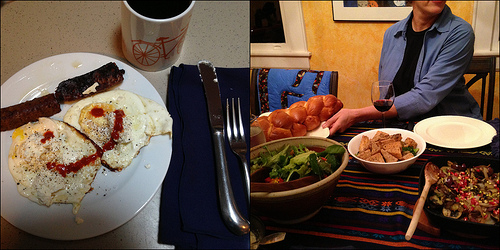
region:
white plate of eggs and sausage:
[1, 46, 173, 241]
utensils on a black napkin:
[195, 54, 258, 246]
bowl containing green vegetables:
[248, 135, 349, 203]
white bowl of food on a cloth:
[348, 120, 426, 172]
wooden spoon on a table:
[405, 156, 444, 246]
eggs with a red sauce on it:
[14, 120, 99, 195]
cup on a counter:
[120, 3, 195, 70]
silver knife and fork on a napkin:
[189, 56, 258, 236]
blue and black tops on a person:
[377, 15, 477, 111]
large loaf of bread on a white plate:
[244, 90, 351, 135]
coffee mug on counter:
[108, 0, 228, 79]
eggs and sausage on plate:
[14, 55, 162, 221]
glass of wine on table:
[349, 68, 408, 137]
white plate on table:
[397, 113, 497, 191]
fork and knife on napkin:
[165, 62, 247, 249]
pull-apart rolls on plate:
[254, 97, 351, 139]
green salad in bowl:
[242, 136, 354, 216]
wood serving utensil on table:
[374, 159, 444, 249]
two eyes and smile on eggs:
[1, 84, 154, 192]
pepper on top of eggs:
[12, 104, 142, 221]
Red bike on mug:
[124, 17, 191, 70]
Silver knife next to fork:
[197, 54, 248, 230]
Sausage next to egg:
[47, 58, 124, 95]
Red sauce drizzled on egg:
[102, 103, 122, 150]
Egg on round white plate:
[72, 96, 153, 166]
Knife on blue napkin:
[197, 56, 247, 231]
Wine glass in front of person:
[367, 76, 399, 135]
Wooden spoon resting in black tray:
[397, 157, 437, 242]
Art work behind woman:
[327, 0, 433, 23]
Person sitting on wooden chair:
[315, 0, 487, 136]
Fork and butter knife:
[198, 62, 251, 235]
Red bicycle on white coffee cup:
[120, 0, 194, 71]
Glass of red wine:
[370, 80, 395, 127]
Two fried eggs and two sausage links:
[0, 53, 171, 240]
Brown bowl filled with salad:
[247, 137, 349, 226]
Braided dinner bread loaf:
[250, 93, 342, 141]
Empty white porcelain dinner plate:
[414, 114, 497, 149]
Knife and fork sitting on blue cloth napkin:
[162, 60, 250, 249]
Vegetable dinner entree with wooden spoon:
[404, 155, 499, 245]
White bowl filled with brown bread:
[347, 126, 424, 170]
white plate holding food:
[2, 51, 171, 238]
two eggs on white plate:
[6, 89, 173, 212]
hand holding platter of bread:
[245, 92, 346, 134]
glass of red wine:
[365, 75, 396, 126]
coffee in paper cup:
[117, 0, 193, 70]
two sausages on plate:
[0, 57, 125, 130]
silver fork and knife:
[193, 58, 251, 228]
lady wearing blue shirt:
[375, 10, 486, 115]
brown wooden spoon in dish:
[405, 158, 438, 240]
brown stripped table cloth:
[337, 174, 404, 245]